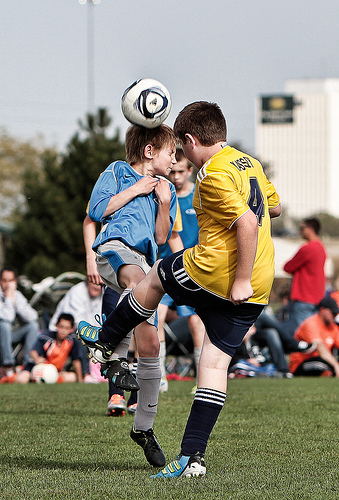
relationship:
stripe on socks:
[193, 386, 228, 407] [176, 384, 224, 456]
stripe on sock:
[127, 295, 150, 318] [98, 290, 153, 349]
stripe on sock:
[127, 295, 150, 318] [178, 387, 226, 456]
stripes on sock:
[126, 294, 160, 329] [182, 387, 225, 454]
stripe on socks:
[193, 388, 226, 403] [179, 388, 223, 456]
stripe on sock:
[127, 288, 169, 324] [86, 289, 159, 354]